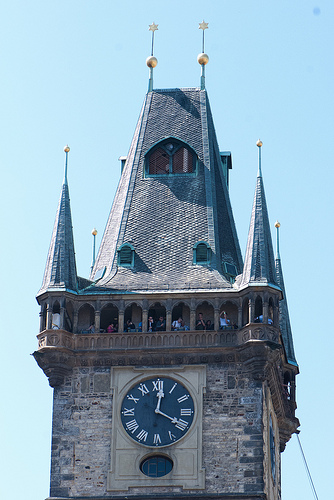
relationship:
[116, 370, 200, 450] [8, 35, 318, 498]
clock on tower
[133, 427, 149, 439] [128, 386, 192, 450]
details on face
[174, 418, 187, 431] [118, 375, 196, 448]
number on face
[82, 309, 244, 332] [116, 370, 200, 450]
people looking out over clock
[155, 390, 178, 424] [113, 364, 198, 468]
hand on clock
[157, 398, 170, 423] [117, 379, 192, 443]
hand on face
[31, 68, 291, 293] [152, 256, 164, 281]
shingles on roof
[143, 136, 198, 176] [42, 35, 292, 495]
window on building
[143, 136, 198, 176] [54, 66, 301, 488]
window on building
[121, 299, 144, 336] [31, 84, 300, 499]
window on building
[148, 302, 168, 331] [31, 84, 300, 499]
window on building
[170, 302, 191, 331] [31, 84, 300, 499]
window on building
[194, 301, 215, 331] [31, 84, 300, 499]
window on building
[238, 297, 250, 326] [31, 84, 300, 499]
window on building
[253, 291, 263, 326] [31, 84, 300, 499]
window on building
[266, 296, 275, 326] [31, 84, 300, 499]
window on building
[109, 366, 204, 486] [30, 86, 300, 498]
clock on tower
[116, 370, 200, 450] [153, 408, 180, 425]
clock has hand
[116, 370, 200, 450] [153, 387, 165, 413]
clock has hand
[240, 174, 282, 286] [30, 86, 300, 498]
steeple on top of tower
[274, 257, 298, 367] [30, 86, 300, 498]
steeple on top of tower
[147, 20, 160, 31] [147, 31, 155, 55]
star on top of pole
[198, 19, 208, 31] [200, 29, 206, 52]
star on top of pole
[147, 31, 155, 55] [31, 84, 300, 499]
pole on top of building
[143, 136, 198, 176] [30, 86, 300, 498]
window on tower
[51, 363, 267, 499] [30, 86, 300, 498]
brick section on tower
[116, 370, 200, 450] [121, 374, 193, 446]
clock has face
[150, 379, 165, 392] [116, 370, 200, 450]
number on clock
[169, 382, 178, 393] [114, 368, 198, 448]
number on clock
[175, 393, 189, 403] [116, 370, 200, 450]
number on clock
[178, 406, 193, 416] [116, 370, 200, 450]
number on clock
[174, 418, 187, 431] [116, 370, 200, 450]
number on clock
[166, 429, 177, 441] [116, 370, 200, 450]
number on clock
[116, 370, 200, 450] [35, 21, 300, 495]
clock on tower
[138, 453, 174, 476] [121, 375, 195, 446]
window beneath clock